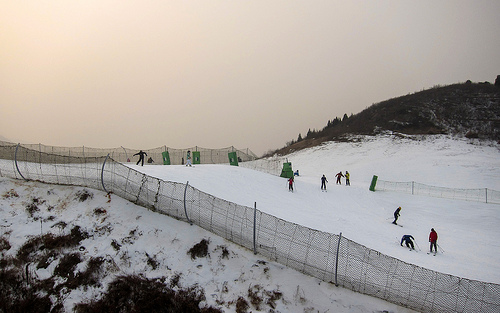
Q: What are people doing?
A: Skiing.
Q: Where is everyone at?
A: A mountian.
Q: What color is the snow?
A: White.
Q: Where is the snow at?
A: On the ground.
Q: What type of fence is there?
A: Net.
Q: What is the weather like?
A: Cloudy.